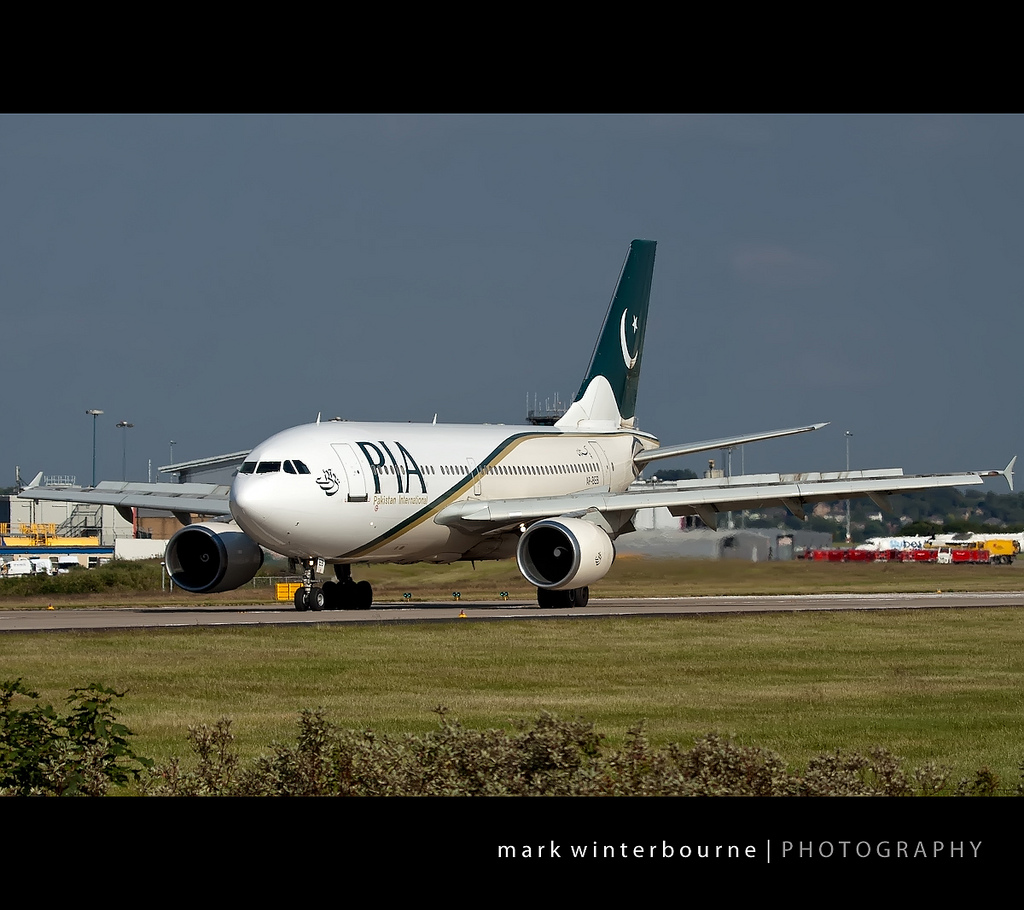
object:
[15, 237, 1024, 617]
airplane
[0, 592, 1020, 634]
runway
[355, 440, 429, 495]
pia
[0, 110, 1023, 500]
sky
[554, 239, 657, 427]
tail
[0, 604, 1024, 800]
grass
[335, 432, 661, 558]
stripes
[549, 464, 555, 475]
windows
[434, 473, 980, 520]
wings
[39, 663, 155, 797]
bushes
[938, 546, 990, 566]
carriers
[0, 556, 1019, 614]
field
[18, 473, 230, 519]
wing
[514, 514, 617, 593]
engine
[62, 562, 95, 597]
shrubs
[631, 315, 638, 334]
star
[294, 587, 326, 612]
landing gear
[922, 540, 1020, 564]
trucks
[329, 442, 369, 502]
door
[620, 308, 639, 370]
moon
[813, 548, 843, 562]
containers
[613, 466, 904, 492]
air vent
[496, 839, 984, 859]
name